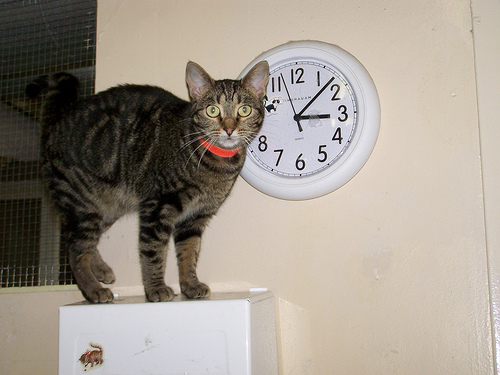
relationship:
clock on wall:
[230, 33, 392, 207] [0, 2, 500, 373]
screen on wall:
[4, 6, 101, 299] [0, 0, 97, 300]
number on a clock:
[288, 67, 306, 85] [230, 33, 392, 207]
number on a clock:
[314, 66, 324, 87] [230, 33, 392, 207]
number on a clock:
[328, 81, 344, 101] [230, 33, 392, 207]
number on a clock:
[330, 124, 344, 147] [230, 33, 392, 207]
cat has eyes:
[1, 59, 270, 302] [204, 96, 260, 122]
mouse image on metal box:
[78, 342, 106, 369] [53, 286, 280, 372]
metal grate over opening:
[2, 10, 87, 270] [2, 6, 103, 290]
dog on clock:
[261, 94, 281, 115] [230, 33, 392, 207]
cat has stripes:
[1, 59, 270, 302] [24, 59, 274, 303]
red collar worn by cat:
[191, 137, 251, 174] [27, 58, 272, 304]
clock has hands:
[230, 38, 380, 201] [277, 67, 346, 135]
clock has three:
[230, 38, 380, 201] [332, 104, 352, 126]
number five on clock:
[317, 142, 328, 163] [230, 33, 392, 207]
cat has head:
[37, 59, 270, 305] [180, 56, 273, 153]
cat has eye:
[37, 59, 270, 305] [233, 103, 254, 117]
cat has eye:
[37, 59, 270, 305] [203, 98, 223, 120]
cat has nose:
[1, 59, 270, 302] [222, 118, 239, 134]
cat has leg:
[37, 59, 270, 305] [129, 199, 187, 316]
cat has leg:
[37, 59, 270, 305] [177, 213, 214, 304]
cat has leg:
[37, 59, 270, 305] [58, 210, 129, 315]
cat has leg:
[37, 59, 270, 305] [85, 223, 123, 288]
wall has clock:
[96, 2, 499, 373] [230, 38, 380, 201]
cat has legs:
[37, 59, 270, 305] [32, 199, 282, 294]